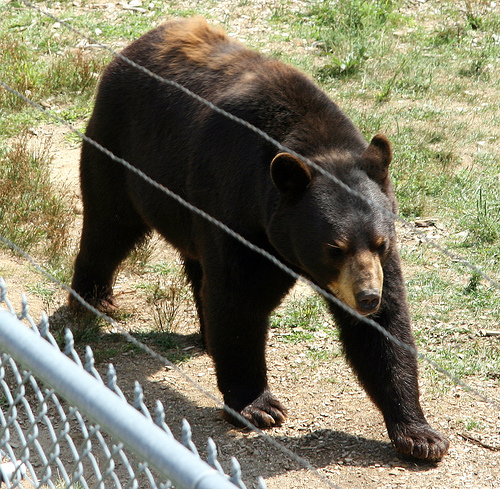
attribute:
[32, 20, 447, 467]
bear — in the picture, fierce , big , female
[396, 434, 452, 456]
claws — in the picture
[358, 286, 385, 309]
nose — in the picture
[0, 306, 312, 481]
shadow — in the picture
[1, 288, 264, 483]
fence — in the picture, chain link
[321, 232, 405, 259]
eyes — in the picture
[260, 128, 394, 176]
ears — in the picture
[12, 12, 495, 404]
wires — in the picture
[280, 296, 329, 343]
grass — in the picture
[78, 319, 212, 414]
dirt — in the picture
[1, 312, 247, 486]
pipe — in the picture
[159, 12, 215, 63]
fur — brown , light, tufts